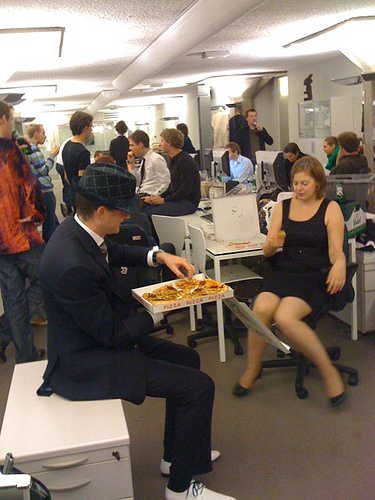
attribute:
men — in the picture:
[106, 129, 196, 199]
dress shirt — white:
[137, 153, 166, 196]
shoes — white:
[159, 446, 235, 499]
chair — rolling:
[326, 222, 367, 393]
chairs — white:
[151, 212, 212, 275]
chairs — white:
[182, 219, 261, 282]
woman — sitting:
[231, 155, 351, 413]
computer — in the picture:
[204, 149, 231, 176]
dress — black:
[253, 197, 331, 312]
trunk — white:
[0, 359, 135, 498]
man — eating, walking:
[59, 111, 132, 194]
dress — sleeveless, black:
[266, 197, 345, 308]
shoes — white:
[157, 450, 246, 498]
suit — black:
[35, 212, 219, 471]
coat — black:
[234, 126, 276, 157]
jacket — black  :
[34, 212, 159, 409]